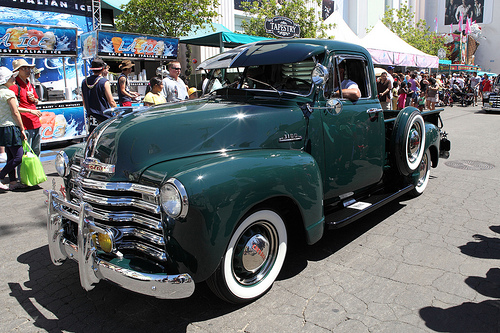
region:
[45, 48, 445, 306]
a teal old fashionedd car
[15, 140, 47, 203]
a neon yellow bag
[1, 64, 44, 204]
two people not looking at the camera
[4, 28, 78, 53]
a sign for italian ice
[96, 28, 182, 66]
a sign for italian ice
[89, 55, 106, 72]
a backwards baseball cap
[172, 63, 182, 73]
a pair of sunglasses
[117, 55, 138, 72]
a brown hat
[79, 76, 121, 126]
a blue sleeveless shirt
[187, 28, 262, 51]
a blue awning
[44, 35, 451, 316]
THE TRUCK IS OLD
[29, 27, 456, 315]
THE TRUCK IS SHINY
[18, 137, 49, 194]
THE GIRL HAS A GREEN BAG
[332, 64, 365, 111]
THE MAN IS DRIVING THE TRUCK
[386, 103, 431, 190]
THE TIRE IS ON THE SIDE OF THE TRUCK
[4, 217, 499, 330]
THE SHADOWS ARE ON THE PAVEMENT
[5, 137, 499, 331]
THE PAVEMENT IS CRACKED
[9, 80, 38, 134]
THE MAN IS WEARING A RED SHIRT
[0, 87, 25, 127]
THE WOMAN IS WEARING A WHITE SHIRT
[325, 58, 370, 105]
THE DRIVER IS WEARING A WHITE SHIRT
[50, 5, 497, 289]
a green truck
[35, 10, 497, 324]
a green antique truck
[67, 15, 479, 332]
a truck on the road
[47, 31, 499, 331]
a green truck on the road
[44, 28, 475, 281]
a green antique truck on road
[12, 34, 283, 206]
people walking on the road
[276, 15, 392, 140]
a person driving the truck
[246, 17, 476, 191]
a person driving green truck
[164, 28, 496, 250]
a person driving antique truck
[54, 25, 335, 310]
a green antique truck parked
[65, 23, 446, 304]
a vintage green truck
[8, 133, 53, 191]
woman holding a green linen bag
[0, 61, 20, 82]
woman wearing a white hat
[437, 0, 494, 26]
an advertisement on the wall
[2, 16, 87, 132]
a stall of Italian ice cream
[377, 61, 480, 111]
people walking in the street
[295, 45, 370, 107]
man driving a vintage truck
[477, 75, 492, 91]
person wearing a red shirt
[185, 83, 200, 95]
boy wearing a yellow cap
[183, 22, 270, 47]
a turquoise canopy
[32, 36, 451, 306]
old green truck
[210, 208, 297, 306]
white walled tires on the truck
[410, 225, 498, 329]
shadows of a crowd on the pavement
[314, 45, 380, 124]
man driving green truck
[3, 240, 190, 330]
shadow of a truck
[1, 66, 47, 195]
woman carrying a green bag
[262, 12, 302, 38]
sign with the word "Tapestry" on it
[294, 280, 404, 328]
cracks in the pavement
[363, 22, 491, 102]
crowd of people in front of a tent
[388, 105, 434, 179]
spare tire on the side of the truck